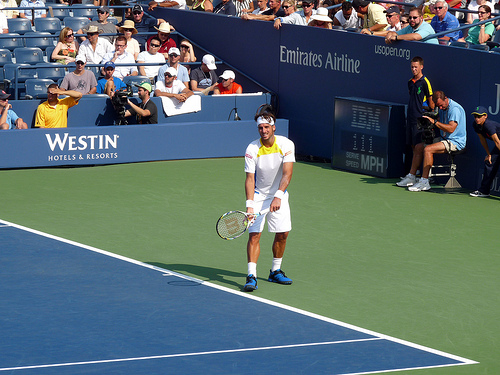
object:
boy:
[469, 106, 499, 198]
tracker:
[334, 89, 409, 180]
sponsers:
[279, 46, 363, 75]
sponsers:
[374, 41, 413, 60]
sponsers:
[46, 131, 119, 162]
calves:
[244, 103, 293, 291]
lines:
[70, 241, 479, 363]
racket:
[216, 207, 269, 241]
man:
[393, 91, 470, 192]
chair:
[427, 144, 465, 187]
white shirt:
[243, 134, 294, 198]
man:
[152, 65, 193, 100]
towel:
[161, 94, 202, 116]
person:
[59, 53, 99, 96]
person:
[376, 57, 434, 179]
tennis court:
[2, 155, 497, 371]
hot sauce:
[55, 15, 201, 101]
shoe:
[243, 273, 260, 292]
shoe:
[269, 267, 293, 284]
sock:
[247, 261, 257, 276]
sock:
[272, 257, 283, 270]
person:
[51, 25, 78, 64]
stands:
[2, 33, 186, 56]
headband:
[255, 116, 274, 125]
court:
[2, 167, 497, 371]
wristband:
[272, 190, 286, 199]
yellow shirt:
[35, 96, 73, 130]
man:
[33, 83, 84, 128]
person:
[125, 82, 160, 123]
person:
[156, 46, 190, 97]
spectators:
[55, 12, 245, 94]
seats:
[0, 17, 124, 96]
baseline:
[0, 219, 482, 373]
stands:
[17, 60, 230, 97]